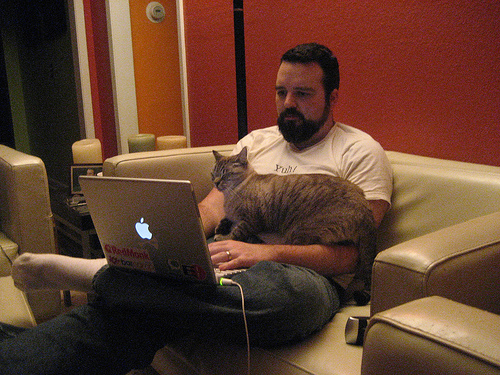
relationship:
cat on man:
[208, 146, 379, 304] [1, 41, 393, 375]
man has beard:
[1, 41, 393, 375] [276, 96, 330, 144]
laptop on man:
[78, 174, 249, 289] [1, 41, 393, 375]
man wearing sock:
[1, 41, 393, 375] [12, 251, 108, 293]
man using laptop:
[1, 41, 393, 375] [78, 174, 249, 289]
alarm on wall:
[147, 2, 165, 22] [73, 2, 499, 167]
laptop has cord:
[78, 174, 249, 289] [218, 276, 250, 375]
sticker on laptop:
[103, 242, 154, 272] [78, 174, 249, 289]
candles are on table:
[70, 134, 189, 165] [50, 196, 104, 264]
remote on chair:
[343, 317, 369, 347] [101, 146, 499, 375]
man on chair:
[1, 41, 393, 375] [101, 146, 499, 375]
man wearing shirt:
[1, 41, 393, 375] [233, 120, 393, 207]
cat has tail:
[208, 146, 379, 304] [353, 212, 376, 306]